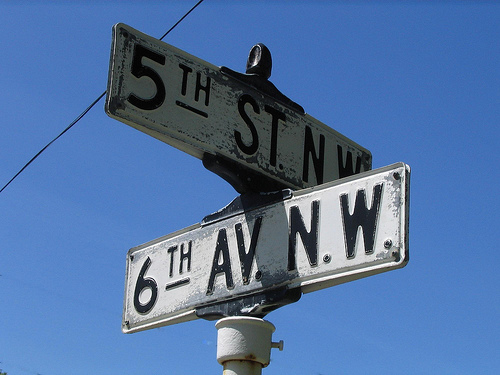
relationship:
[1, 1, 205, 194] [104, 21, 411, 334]
power line above sign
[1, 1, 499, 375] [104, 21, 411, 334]
sky behind sign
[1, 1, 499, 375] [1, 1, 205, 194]
sky behind power line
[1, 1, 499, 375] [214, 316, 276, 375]
sky behind pole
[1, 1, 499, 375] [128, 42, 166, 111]
sky behind number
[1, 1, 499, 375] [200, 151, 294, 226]
sky behind brackets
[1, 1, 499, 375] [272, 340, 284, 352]
sky behind screw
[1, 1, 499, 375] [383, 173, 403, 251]
sky behind bolts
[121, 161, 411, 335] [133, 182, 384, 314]
sign has letter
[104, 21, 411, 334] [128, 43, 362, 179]
sign has letter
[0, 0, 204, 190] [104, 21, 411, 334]
power line above sign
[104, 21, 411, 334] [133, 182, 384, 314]
sign with letter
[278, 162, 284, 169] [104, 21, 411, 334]
nail on sign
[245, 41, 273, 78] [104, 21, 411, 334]
cap on sign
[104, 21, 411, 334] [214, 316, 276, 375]
sign on top of pole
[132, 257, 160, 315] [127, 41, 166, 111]
number 6 under number 5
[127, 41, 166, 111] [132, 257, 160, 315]
number 5 on top of number 6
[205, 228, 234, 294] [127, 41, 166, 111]
letter a under number 5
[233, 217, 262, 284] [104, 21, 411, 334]
letter v under sign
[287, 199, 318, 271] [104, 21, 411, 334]
letter n under sign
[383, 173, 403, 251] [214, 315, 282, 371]
bolts on pole